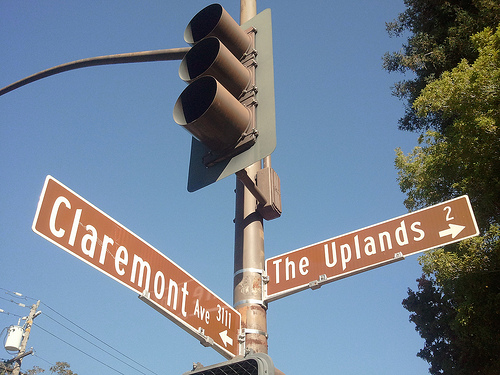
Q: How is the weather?
A: It is clear.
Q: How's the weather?
A: It is clear.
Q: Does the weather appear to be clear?
A: Yes, it is clear.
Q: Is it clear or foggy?
A: It is clear.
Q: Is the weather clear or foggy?
A: It is clear.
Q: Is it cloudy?
A: No, it is clear.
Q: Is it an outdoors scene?
A: Yes, it is outdoors.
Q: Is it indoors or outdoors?
A: It is outdoors.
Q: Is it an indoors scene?
A: No, it is outdoors.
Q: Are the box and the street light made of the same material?
A: Yes, both the box and the street light are made of metal.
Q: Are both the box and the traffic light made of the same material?
A: Yes, both the box and the traffic light are made of metal.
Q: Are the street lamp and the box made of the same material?
A: Yes, both the street lamp and the box are made of metal.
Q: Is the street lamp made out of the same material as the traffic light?
A: Yes, both the street lamp and the traffic light are made of metal.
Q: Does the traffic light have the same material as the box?
A: Yes, both the traffic light and the box are made of metal.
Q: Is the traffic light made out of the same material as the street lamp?
A: Yes, both the traffic light and the street lamp are made of metal.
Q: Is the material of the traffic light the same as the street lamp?
A: Yes, both the traffic light and the street lamp are made of metal.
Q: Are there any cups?
A: No, there are no cups.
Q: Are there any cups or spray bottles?
A: No, there are no cups or spray bottles.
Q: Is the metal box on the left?
A: Yes, the box is on the left of the image.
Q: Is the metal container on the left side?
A: Yes, the box is on the left of the image.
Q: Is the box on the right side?
A: No, the box is on the left of the image.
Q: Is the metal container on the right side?
A: No, the box is on the left of the image.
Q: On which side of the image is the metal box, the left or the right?
A: The box is on the left of the image.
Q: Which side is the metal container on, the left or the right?
A: The box is on the left of the image.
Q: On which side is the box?
A: The box is on the left of the image.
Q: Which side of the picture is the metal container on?
A: The box is on the left of the image.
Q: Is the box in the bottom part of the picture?
A: Yes, the box is in the bottom of the image.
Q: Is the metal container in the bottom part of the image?
A: Yes, the box is in the bottom of the image.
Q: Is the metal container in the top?
A: No, the box is in the bottom of the image.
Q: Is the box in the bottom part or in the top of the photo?
A: The box is in the bottom of the image.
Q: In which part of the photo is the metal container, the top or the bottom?
A: The box is in the bottom of the image.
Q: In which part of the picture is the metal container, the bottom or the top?
A: The box is in the bottom of the image.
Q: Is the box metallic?
A: Yes, the box is metallic.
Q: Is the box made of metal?
A: Yes, the box is made of metal.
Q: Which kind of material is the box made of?
A: The box is made of metal.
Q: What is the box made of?
A: The box is made of metal.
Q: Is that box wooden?
A: No, the box is metallic.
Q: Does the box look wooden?
A: No, the box is metallic.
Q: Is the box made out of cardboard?
A: No, the box is made of metal.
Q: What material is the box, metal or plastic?
A: The box is made of metal.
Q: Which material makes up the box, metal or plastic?
A: The box is made of metal.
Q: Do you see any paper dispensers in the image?
A: No, there are no paper dispensers.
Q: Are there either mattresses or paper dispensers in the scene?
A: No, there are no paper dispensers or mattresses.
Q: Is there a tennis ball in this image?
A: No, there are no tennis balls.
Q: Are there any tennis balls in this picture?
A: No, there are no tennis balls.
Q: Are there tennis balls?
A: No, there are no tennis balls.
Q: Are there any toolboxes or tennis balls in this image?
A: No, there are no tennis balls or toolboxes.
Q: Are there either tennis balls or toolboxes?
A: No, there are no tennis balls or toolboxes.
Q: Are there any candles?
A: No, there are no candles.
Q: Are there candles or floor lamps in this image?
A: No, there are no candles or floor lamps.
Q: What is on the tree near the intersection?
A: The leaves are on the tree.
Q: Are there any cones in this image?
A: No, there are no cones.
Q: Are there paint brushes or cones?
A: No, there are no cones or paint brushes.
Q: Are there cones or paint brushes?
A: No, there are no cones or paint brushes.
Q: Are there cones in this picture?
A: No, there are no cones.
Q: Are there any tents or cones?
A: No, there are no cones or tents.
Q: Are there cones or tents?
A: No, there are no cones or tents.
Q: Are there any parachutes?
A: No, there are no parachutes.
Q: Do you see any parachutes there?
A: No, there are no parachutes.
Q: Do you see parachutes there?
A: No, there are no parachutes.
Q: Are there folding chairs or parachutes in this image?
A: No, there are no parachutes or folding chairs.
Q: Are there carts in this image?
A: No, there are no carts.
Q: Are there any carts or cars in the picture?
A: No, there are no carts or cars.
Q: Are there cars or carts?
A: No, there are no carts or cars.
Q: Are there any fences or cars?
A: No, there are no cars or fences.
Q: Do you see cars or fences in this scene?
A: No, there are no cars or fences.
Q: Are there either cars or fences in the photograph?
A: No, there are no cars or fences.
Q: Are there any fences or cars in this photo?
A: No, there are no cars or fences.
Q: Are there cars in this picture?
A: No, there are no cars.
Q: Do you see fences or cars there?
A: No, there are no cars or fences.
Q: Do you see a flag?
A: No, there are no flags.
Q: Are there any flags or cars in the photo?
A: No, there are no flags or cars.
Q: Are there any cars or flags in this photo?
A: No, there are no flags or cars.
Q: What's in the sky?
A: The wire is in the sky.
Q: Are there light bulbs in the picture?
A: No, there are no light bulbs.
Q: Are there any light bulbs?
A: No, there are no light bulbs.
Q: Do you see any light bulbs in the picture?
A: No, there are no light bulbs.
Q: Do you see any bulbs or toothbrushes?
A: No, there are no bulbs or toothbrushes.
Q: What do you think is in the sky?
A: The wire is in the sky.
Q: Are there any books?
A: No, there are no books.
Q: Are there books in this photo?
A: No, there are no books.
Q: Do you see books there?
A: No, there are no books.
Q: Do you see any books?
A: No, there are no books.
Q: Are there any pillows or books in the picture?
A: No, there are no books or pillows.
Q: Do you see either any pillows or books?
A: No, there are no books or pillows.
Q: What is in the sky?
A: The wire is in the sky.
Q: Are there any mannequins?
A: No, there are no mannequins.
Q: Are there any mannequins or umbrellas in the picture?
A: No, there are no mannequins or umbrellas.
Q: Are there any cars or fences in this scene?
A: No, there are no cars or fences.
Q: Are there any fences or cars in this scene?
A: No, there are no cars or fences.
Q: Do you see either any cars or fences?
A: No, there are no cars or fences.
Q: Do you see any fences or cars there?
A: No, there are no cars or fences.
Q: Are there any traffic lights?
A: Yes, there is a traffic light.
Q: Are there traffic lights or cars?
A: Yes, there is a traffic light.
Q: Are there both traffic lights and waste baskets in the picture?
A: No, there is a traffic light but no waste baskets.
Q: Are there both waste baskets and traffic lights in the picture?
A: No, there is a traffic light but no waste baskets.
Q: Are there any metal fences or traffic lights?
A: Yes, there is a metal traffic light.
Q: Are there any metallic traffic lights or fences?
A: Yes, there is a metal traffic light.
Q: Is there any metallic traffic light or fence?
A: Yes, there is a metal traffic light.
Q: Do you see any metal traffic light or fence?
A: Yes, there is a metal traffic light.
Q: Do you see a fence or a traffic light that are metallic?
A: Yes, the traffic light is metallic.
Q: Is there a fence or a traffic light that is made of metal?
A: Yes, the traffic light is made of metal.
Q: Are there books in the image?
A: No, there are no books.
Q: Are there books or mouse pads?
A: No, there are no books or mouse pads.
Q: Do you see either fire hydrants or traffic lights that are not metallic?
A: No, there is a traffic light but it is metallic.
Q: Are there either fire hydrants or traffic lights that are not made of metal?
A: No, there is a traffic light but it is made of metal.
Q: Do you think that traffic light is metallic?
A: Yes, the traffic light is metallic.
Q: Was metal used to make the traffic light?
A: Yes, the traffic light is made of metal.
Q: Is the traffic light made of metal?
A: Yes, the traffic light is made of metal.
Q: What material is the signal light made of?
A: The signal light is made of metal.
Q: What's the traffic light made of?
A: The signal light is made of metal.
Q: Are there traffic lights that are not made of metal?
A: No, there is a traffic light but it is made of metal.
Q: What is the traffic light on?
A: The traffic light is on the pole.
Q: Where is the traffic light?
A: The traffic light is at the intersection.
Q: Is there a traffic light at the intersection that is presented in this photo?
A: Yes, there is a traffic light at the intersection.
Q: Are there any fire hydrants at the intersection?
A: No, there is a traffic light at the intersection.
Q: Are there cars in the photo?
A: No, there are no cars.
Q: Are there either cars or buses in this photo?
A: No, there are no cars or buses.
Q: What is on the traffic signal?
A: The sign is on the traffic signal.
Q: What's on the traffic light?
A: The sign is on the traffic signal.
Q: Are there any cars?
A: No, there are no cars.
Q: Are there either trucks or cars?
A: No, there are no cars or trucks.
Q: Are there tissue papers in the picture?
A: No, there are no tissue papers.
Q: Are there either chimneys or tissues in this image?
A: No, there are no tissues or chimneys.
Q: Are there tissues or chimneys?
A: No, there are no tissues or chimneys.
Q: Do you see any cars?
A: No, there are no cars.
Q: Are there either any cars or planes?
A: No, there are no cars or planes.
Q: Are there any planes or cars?
A: No, there are no cars or planes.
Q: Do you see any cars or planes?
A: No, there are no cars or planes.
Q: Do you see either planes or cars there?
A: No, there are no cars or planes.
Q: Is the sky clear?
A: Yes, the sky is clear.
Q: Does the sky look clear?
A: Yes, the sky is clear.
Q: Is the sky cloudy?
A: No, the sky is clear.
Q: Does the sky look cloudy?
A: No, the sky is clear.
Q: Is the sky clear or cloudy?
A: The sky is clear.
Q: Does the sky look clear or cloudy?
A: The sky is clear.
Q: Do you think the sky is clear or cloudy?
A: The sky is clear.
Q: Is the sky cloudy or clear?
A: The sky is clear.